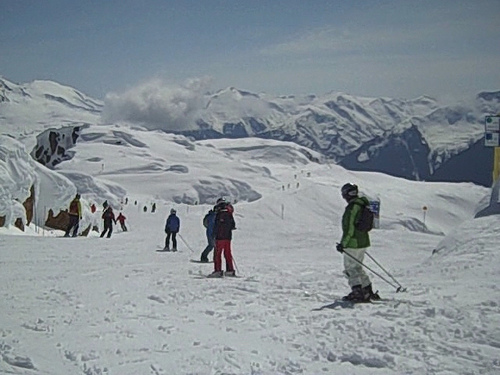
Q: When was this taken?
A: Daytime.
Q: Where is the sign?
A: Far right.